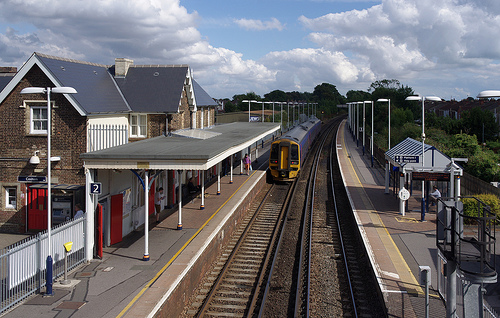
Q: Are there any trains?
A: Yes, there is a train.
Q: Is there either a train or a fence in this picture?
A: Yes, there is a train.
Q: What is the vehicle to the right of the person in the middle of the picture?
A: The vehicle is a train.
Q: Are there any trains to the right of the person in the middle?
A: Yes, there is a train to the right of the person.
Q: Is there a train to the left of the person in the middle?
A: No, the train is to the right of the person.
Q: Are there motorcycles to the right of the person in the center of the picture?
A: No, there is a train to the right of the person.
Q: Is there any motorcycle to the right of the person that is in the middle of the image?
A: No, there is a train to the right of the person.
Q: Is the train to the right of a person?
A: Yes, the train is to the right of a person.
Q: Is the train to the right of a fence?
A: No, the train is to the right of a person.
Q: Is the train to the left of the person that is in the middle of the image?
A: No, the train is to the right of the person.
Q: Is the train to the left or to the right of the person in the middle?
A: The train is to the right of the person.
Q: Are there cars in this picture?
A: No, there are no cars.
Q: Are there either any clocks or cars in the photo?
A: No, there are no cars or clocks.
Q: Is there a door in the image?
A: Yes, there is a door.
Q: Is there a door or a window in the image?
A: Yes, there is a door.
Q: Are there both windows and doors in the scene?
A: Yes, there are both a door and a window.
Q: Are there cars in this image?
A: No, there are no cars.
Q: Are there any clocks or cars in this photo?
A: No, there are no cars or clocks.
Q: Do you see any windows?
A: Yes, there is a window.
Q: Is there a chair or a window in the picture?
A: Yes, there is a window.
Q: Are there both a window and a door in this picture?
A: Yes, there are both a window and a door.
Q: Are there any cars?
A: No, there are no cars.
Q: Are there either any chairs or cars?
A: No, there are no cars or chairs.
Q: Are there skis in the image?
A: No, there are no skis.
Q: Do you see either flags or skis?
A: No, there are no skis or flags.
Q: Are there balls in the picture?
A: No, there are no balls.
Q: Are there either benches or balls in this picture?
A: No, there are no balls or benches.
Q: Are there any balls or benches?
A: No, there are no balls or benches.